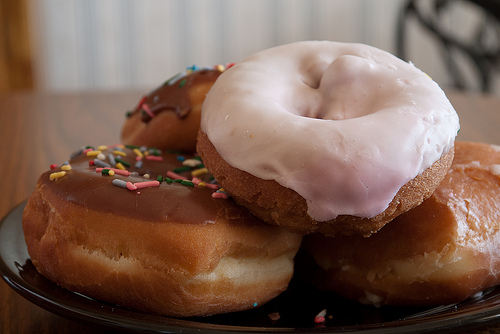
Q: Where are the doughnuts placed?
A: On a plate.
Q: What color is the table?
A: Brown.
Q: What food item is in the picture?
A: Doughnuts.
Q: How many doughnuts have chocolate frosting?
A: Two.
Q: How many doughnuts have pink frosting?
A: One.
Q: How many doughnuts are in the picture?
A: Four.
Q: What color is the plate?
A: Black.